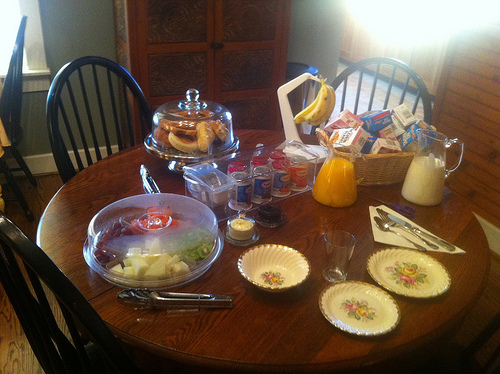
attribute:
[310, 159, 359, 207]
juice — orange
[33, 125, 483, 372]
table — wooden, set, dark, brown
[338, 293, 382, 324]
flowers — colorful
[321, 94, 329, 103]
spots — brown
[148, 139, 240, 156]
tray — silver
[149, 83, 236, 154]
lid — glass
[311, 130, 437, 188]
basket — wicker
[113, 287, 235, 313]
tongs — silver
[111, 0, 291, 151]
cabinet — dark, brown, wooden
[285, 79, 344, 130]
bananas — yellow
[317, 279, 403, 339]
plate — floral, small, white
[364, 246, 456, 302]
plate — white, small, floral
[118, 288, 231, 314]
tongs — silver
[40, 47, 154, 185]
chair — wooden, black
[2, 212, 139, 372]
chair — black, wooden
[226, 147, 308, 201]
yogurt — in cold case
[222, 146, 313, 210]
yogurt — in cold case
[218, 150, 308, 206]
yogurt — in cold case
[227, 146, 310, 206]
yogurt — in cold case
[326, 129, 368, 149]
cereal box — in basket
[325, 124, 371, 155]
cereal box — in basket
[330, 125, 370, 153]
cereal box — in basket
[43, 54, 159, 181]
chair — dining room, black , wooden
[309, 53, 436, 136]
dining room/chair — wooden, black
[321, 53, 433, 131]
dining room/chair — black, wooden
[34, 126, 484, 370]
kitchen table — dark brown, wooden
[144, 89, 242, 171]
platter — with donuts under a glass top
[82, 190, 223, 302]
fruit/cheese tray — covered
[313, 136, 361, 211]
container — of orange juice, on the table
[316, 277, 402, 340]
floral plate — small , white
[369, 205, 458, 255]
silverware setting — on a white napkin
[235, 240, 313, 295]
bowl — white, small, floral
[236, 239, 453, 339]
dishes — floral print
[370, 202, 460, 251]
silverware — on the napkin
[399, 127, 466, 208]
pitcher — of milk, on the table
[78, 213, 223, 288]
tray — plastic